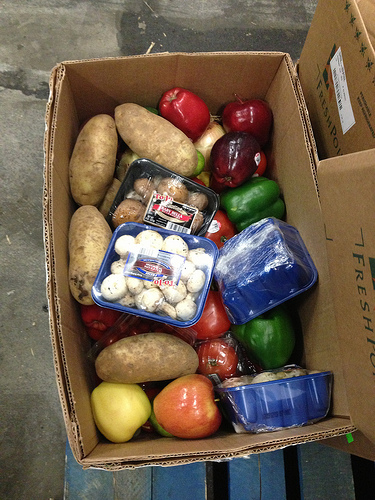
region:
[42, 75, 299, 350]
The box contains fruits and vegetables.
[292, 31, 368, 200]
The box is cardboard.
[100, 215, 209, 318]
The mushrooms is white.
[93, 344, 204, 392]
The potato is near the apple.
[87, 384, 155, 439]
The apple is yellow.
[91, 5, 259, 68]
The sidewalk is dirty.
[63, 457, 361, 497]
The table is blue.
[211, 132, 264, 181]
The apples is red.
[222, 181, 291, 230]
The green pepper in the carton.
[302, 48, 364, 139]
A white label on the box.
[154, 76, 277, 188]
red apples in a box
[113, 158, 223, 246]
a carton of brown mushrooms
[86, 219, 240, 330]
a carton of white mushrooms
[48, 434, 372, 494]
a pallet holding a box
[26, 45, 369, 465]
a box of vegetables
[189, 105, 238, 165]
an onion under an apple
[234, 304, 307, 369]
a green peper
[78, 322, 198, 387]
a potato next to a yellow apple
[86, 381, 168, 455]
a yellow apple by a potato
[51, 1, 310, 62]
a stained concrete floor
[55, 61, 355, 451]
Cardboard box with fruits and vegetables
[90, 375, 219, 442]
A golden apple next to a red apple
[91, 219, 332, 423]
Three blue containers full of mushrooms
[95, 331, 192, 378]
A large baking potato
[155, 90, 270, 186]
Three red apples on top of an onion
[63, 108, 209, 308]
3 large potatoes and 2 packages of mushrooms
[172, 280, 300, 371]
A green bell pepper, a tomato and a red bell pepper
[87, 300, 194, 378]
A large potato on top of a package of cherry tomatoes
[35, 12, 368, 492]
Three boxes of fruits and vegetables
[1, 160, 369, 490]
The boxes are sitting on a blue pallet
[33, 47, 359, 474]
cardboard box of vegetables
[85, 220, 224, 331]
blue box of vegetables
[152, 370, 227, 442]
red apple in a box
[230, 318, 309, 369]
green pepper in a box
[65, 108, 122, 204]
potato in a box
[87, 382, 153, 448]
yellow apple in a box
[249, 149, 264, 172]
sticker on an apple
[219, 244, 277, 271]
cellophane over blue box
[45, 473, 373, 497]
blue wooden pallet on the ground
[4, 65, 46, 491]
grey cement ground under the boxes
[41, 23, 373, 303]
a box of fruit and vegetable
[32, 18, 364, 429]
a cardboard box full of vegetables and fruit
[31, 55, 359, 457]
fruit and vegetables in a cardboard box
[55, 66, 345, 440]
a mix of fruit and vegetables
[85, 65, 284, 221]
potato mushroom apple green pepper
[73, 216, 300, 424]
mushroom apple tomato potato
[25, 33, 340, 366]
a container of mixed vegetables and fruit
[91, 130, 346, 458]
three containers of mushroom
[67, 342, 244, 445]
red and green apples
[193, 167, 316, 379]
two green peppers